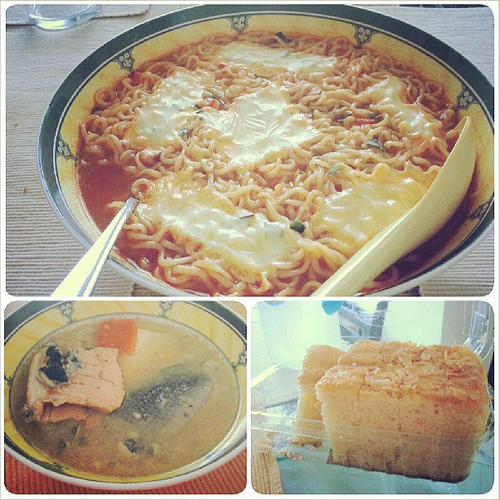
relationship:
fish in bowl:
[107, 361, 223, 464] [1, 351, 229, 478]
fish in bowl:
[26, 342, 127, 426] [7, 303, 245, 485]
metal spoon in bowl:
[47, 195, 140, 298] [38, 77, 484, 285]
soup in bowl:
[153, 79, 469, 278] [57, 9, 488, 317]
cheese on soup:
[221, 74, 326, 165] [113, 97, 325, 245]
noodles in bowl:
[98, 90, 145, 157] [39, 1, 494, 293]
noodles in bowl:
[270, 167, 310, 209] [39, 1, 494, 293]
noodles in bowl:
[311, 84, 380, 128] [39, 1, 494, 293]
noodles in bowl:
[127, 223, 213, 280] [39, 1, 494, 293]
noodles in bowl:
[302, 39, 341, 58] [39, 1, 494, 293]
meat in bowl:
[27, 341, 127, 427] [4, 301, 244, 447]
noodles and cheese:
[174, 123, 338, 231] [152, 84, 308, 156]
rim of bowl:
[37, 25, 126, 237] [61, 38, 499, 317]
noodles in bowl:
[143, 247, 195, 285] [39, 1, 494, 293]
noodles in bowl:
[127, 155, 164, 173] [39, 1, 494, 293]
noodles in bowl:
[275, 250, 313, 282] [39, 1, 494, 293]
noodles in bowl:
[370, 145, 411, 162] [39, 1, 494, 293]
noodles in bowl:
[306, 169, 326, 191] [39, 1, 494, 293]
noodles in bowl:
[83, 33, 458, 297] [39, 1, 494, 293]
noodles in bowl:
[152, 72, 377, 259] [49, 10, 178, 280]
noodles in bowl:
[270, 179, 320, 219] [39, 1, 494, 293]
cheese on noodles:
[205, 116, 333, 200] [254, 54, 438, 205]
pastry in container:
[289, 329, 495, 486] [253, 357, 483, 490]